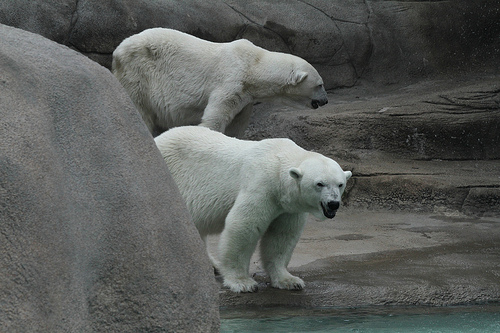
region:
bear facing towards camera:
[128, 119, 365, 310]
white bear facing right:
[104, 19, 339, 150]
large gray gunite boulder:
[2, 15, 242, 331]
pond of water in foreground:
[213, 285, 498, 329]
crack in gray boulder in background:
[292, 0, 385, 80]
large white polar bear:
[145, 120, 358, 290]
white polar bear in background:
[107, 17, 339, 149]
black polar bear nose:
[325, 196, 340, 213]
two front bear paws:
[216, 256, 309, 300]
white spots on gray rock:
[387, 116, 494, 158]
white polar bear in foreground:
[139, 121, 356, 307]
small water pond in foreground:
[216, 288, 496, 331]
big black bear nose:
[323, 195, 341, 217]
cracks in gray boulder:
[298, 1, 408, 84]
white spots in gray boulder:
[396, 125, 486, 162]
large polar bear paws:
[215, 266, 307, 299]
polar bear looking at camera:
[147, 113, 371, 298]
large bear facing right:
[97, 10, 340, 142]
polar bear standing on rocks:
[44, 8, 434, 329]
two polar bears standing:
[79, 11, 429, 332]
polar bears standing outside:
[67, 3, 422, 330]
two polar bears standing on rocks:
[68, 8, 414, 331]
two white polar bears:
[69, 15, 409, 330]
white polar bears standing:
[83, 26, 390, 325]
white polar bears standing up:
[83, 15, 415, 325]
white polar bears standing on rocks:
[47, 6, 425, 332]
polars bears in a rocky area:
[68, 19, 450, 319]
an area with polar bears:
[71, 11, 489, 311]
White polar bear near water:
[153, 121, 366, 266]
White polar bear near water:
[228, 144, 375, 331]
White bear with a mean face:
[290, 160, 345, 224]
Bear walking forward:
[111, 23, 339, 141]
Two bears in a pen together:
[96, 29, 365, 283]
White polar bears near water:
[108, 30, 345, 267]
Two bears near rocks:
[114, 30, 357, 264]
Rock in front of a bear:
[161, 104, 340, 288]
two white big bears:
[112, 27, 351, 301]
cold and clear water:
[218, 299, 498, 330]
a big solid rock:
[1, 24, 217, 331]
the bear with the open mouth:
[293, 157, 350, 224]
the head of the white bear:
[293, 148, 350, 220]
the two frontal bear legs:
[222, 204, 307, 297]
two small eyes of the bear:
[314, 179, 345, 191]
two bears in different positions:
[116, 34, 346, 295]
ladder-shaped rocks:
[369, 34, 496, 240]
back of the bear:
[138, 24, 252, 54]